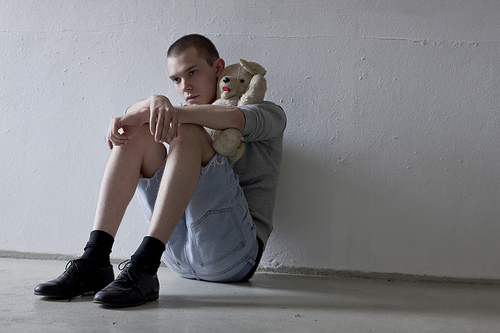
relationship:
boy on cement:
[140, 40, 320, 164] [174, 291, 281, 332]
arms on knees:
[118, 99, 200, 129] [133, 121, 218, 148]